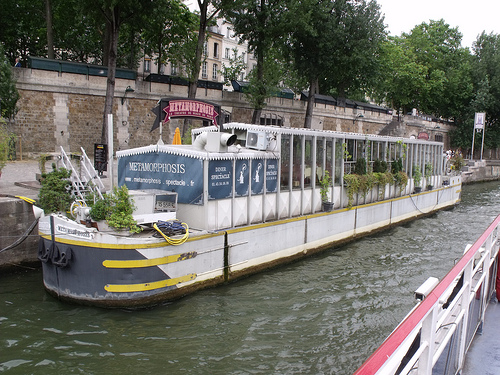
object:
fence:
[352, 214, 500, 375]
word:
[129, 162, 186, 173]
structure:
[32, 121, 461, 310]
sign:
[162, 99, 219, 128]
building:
[128, 0, 293, 91]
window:
[213, 42, 219, 59]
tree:
[0, 0, 195, 145]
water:
[0, 178, 500, 375]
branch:
[99, 2, 120, 60]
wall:
[0, 65, 500, 157]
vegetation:
[85, 179, 145, 235]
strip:
[38, 228, 174, 249]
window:
[280, 133, 293, 191]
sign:
[470, 112, 486, 161]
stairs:
[59, 144, 105, 206]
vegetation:
[319, 169, 333, 203]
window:
[314, 135, 325, 187]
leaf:
[135, 15, 137, 17]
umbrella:
[172, 127, 181, 145]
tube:
[192, 132, 237, 153]